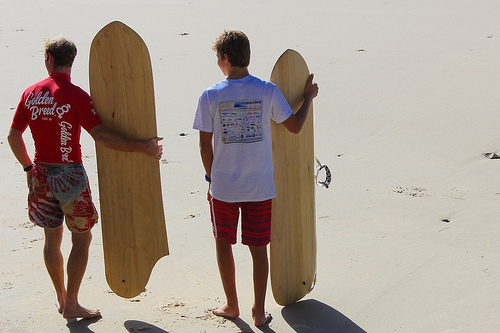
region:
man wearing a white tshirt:
[192, 73, 296, 210]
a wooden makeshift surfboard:
[255, 41, 321, 307]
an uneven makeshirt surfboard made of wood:
[85, 13, 171, 300]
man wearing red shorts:
[202, 191, 275, 251]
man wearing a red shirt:
[14, 73, 102, 163]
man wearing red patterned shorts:
[22, 153, 104, 233]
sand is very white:
[1, 4, 498, 331]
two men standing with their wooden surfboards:
[12, 15, 332, 323]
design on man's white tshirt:
[216, 92, 267, 147]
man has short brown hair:
[213, 29, 254, 69]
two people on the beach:
[0, 12, 345, 193]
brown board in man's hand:
[222, 52, 361, 291]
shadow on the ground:
[323, 273, 391, 330]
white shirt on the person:
[166, 32, 307, 162]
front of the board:
[73, 9, 163, 81]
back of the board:
[91, 178, 197, 304]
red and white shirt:
[3, 63, 111, 175]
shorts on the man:
[16, 150, 108, 245]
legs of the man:
[16, 217, 122, 314]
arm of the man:
[88, 115, 170, 174]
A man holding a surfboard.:
[9, 19, 169, 320]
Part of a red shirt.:
[39, 130, 50, 153]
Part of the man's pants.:
[33, 201, 49, 218]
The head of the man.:
[44, 37, 76, 76]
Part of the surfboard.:
[97, 35, 129, 78]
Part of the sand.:
[411, 122, 449, 169]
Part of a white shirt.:
[229, 162, 254, 186]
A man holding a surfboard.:
[192, 30, 319, 327]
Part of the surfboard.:
[285, 252, 299, 277]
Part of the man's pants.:
[254, 214, 271, 239]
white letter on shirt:
[58, 118, 72, 129]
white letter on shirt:
[48, 99, 56, 116]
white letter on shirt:
[44, 104, 49, 115]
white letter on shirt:
[38, 103, 48, 113]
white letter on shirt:
[36, 103, 46, 118]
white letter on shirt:
[28, 103, 38, 123]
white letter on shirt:
[21, 89, 35, 106]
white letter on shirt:
[43, 94, 53, 106]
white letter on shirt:
[58, 144, 73, 153]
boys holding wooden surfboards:
[20, 13, 345, 328]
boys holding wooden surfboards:
[23, 16, 334, 329]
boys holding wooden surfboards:
[8, 4, 350, 328]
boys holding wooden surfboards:
[2, 25, 336, 324]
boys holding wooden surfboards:
[5, 14, 325, 329]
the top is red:
[5, 71, 96, 185]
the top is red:
[6, 70, 122, 210]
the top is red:
[13, 74, 135, 211]